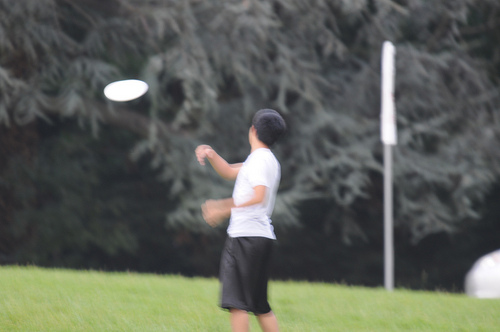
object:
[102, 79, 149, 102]
frisbee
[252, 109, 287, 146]
hair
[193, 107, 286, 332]
boy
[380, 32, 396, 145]
sign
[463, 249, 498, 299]
rock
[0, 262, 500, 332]
grass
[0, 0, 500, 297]
foliage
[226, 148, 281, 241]
shirt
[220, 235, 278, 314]
shorts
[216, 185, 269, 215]
arm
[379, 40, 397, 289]
pole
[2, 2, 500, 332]
park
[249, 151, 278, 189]
sleeves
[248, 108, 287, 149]
head